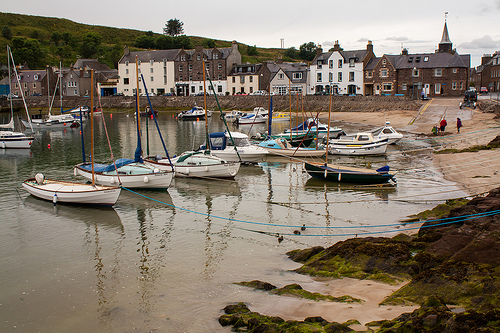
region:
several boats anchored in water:
[2, 38, 407, 219]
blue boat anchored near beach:
[300, 155, 401, 192]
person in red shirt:
[435, 115, 450, 132]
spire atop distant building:
[436, 10, 454, 50]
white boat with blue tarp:
[70, 151, 177, 189]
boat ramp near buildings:
[407, 92, 477, 132]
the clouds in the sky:
[3, 0, 499, 58]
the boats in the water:
[1, 55, 401, 214]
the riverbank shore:
[220, 100, 488, 331]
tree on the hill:
[162, 13, 186, 40]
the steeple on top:
[439, 7, 452, 26]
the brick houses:
[365, 32, 472, 101]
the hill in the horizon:
[0, 13, 270, 64]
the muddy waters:
[250, 242, 419, 324]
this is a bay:
[50, 39, 441, 241]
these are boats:
[31, 95, 281, 262]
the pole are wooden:
[63, 79, 213, 160]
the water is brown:
[33, 222, 253, 329]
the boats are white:
[80, 137, 286, 219]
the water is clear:
[113, 221, 386, 331]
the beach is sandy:
[425, 113, 488, 170]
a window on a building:
[216, 84, 223, 95]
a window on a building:
[293, 70, 300, 81]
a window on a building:
[347, 71, 359, 87]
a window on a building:
[412, 67, 422, 85]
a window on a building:
[436, 65, 443, 77]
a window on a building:
[125, 78, 135, 87]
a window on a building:
[25, 84, 30, 86]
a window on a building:
[71, 82, 83, 89]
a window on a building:
[125, 69, 132, 76]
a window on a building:
[246, 74, 256, 82]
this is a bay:
[53, 95, 334, 261]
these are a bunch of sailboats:
[85, 136, 326, 246]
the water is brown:
[80, 200, 205, 280]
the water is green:
[26, 138, 86, 173]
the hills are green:
[20, 12, 160, 73]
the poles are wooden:
[65, 63, 272, 163]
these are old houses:
[190, 45, 460, 121]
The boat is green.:
[305, 159, 394, 187]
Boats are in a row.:
[23, 147, 377, 208]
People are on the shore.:
[431, 117, 463, 139]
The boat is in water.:
[296, 152, 398, 192]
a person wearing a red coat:
[436, 113, 448, 133]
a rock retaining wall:
[5, 90, 498, 121]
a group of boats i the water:
[1, 99, 416, 218]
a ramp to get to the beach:
[403, 91, 474, 129]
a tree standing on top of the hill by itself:
[160, 15, 185, 35]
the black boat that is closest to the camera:
[295, 151, 400, 187]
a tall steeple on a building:
[435, 10, 459, 56]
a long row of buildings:
[1, 41, 498, 106]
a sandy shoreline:
[283, 105, 498, 201]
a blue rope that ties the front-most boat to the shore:
[111, 178, 498, 245]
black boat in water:
[301, 160, 400, 192]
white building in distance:
[305, 43, 370, 100]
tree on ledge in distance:
[159, 17, 183, 42]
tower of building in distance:
[435, 9, 450, 52]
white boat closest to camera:
[22, 173, 125, 211]